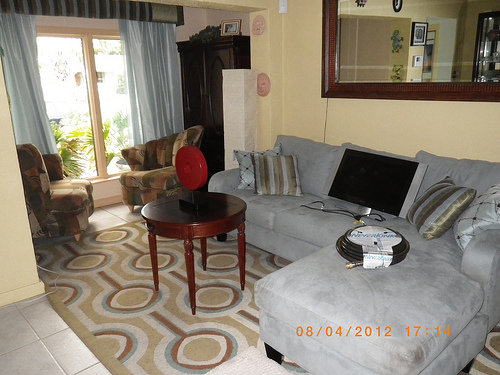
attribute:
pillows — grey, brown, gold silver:
[228, 142, 499, 248]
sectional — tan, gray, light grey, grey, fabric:
[207, 132, 499, 374]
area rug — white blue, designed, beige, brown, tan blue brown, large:
[31, 216, 293, 374]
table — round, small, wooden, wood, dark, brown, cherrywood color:
[142, 188, 247, 311]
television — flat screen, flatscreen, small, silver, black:
[326, 145, 428, 222]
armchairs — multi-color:
[16, 123, 204, 237]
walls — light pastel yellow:
[214, 0, 498, 164]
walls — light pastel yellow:
[1, 54, 45, 308]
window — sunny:
[93, 36, 134, 175]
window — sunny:
[35, 36, 98, 180]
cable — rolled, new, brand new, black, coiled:
[335, 223, 409, 272]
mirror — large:
[336, 1, 499, 80]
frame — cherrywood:
[320, 0, 499, 102]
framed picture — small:
[217, 17, 243, 37]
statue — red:
[174, 144, 210, 212]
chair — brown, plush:
[118, 124, 206, 211]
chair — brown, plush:
[16, 142, 94, 238]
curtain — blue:
[118, 18, 184, 149]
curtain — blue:
[1, 13, 59, 154]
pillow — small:
[251, 152, 304, 199]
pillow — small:
[231, 140, 282, 190]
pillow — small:
[405, 173, 476, 239]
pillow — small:
[452, 179, 499, 246]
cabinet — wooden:
[174, 35, 251, 191]